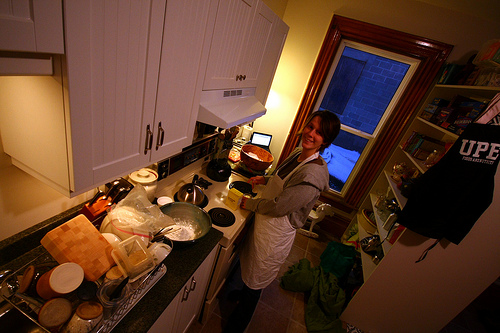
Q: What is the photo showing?
A: It is showing a kitchen.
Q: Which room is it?
A: It is a kitchen.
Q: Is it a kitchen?
A: Yes, it is a kitchen.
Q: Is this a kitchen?
A: Yes, it is a kitchen.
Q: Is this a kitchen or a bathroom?
A: It is a kitchen.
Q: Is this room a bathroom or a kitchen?
A: It is a kitchen.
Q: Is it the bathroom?
A: No, it is the kitchen.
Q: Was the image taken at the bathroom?
A: No, the picture was taken in the kitchen.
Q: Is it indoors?
A: Yes, it is indoors.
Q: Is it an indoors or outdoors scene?
A: It is indoors.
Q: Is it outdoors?
A: No, it is indoors.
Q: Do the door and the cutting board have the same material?
A: No, the door is made of glass and the cutting board is made of wood.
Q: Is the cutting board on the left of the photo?
A: Yes, the cutting board is on the left of the image.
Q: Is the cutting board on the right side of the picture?
A: No, the cutting board is on the left of the image.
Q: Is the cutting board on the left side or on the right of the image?
A: The cutting board is on the left of the image.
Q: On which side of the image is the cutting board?
A: The cutting board is on the left of the image.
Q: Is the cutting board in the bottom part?
A: Yes, the cutting board is in the bottom of the image.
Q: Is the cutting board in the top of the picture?
A: No, the cutting board is in the bottom of the image.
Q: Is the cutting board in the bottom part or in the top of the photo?
A: The cutting board is in the bottom of the image.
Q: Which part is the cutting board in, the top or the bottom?
A: The cutting board is in the bottom of the image.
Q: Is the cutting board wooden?
A: Yes, the cutting board is wooden.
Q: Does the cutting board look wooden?
A: Yes, the cutting board is wooden.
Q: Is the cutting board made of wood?
A: Yes, the cutting board is made of wood.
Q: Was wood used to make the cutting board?
A: Yes, the cutting board is made of wood.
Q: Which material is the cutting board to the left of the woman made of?
A: The cutting board is made of wood.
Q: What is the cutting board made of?
A: The cutting board is made of wood.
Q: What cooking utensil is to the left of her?
A: The cooking utensil is a cutting board.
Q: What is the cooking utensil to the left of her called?
A: The cooking utensil is a cutting board.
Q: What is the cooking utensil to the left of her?
A: The cooking utensil is a cutting board.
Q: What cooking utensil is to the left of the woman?
A: The cooking utensil is a cutting board.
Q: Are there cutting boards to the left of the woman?
A: Yes, there is a cutting board to the left of the woman.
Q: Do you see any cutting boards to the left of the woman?
A: Yes, there is a cutting board to the left of the woman.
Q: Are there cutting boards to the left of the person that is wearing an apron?
A: Yes, there is a cutting board to the left of the woman.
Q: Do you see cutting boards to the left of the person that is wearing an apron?
A: Yes, there is a cutting board to the left of the woman.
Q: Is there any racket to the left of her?
A: No, there is a cutting board to the left of the woman.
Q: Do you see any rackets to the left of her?
A: No, there is a cutting board to the left of the woman.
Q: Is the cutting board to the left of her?
A: Yes, the cutting board is to the left of the woman.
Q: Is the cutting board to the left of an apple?
A: No, the cutting board is to the left of the woman.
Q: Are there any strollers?
A: No, there are no strollers.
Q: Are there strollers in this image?
A: No, there are no strollers.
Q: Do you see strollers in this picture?
A: No, there are no strollers.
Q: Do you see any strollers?
A: No, there are no strollers.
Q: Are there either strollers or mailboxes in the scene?
A: No, there are no strollers or mailboxes.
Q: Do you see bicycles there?
A: No, there are no bicycles.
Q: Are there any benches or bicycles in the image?
A: No, there are no bicycles or benches.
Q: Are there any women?
A: Yes, there is a woman.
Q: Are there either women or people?
A: Yes, there is a woman.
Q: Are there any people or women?
A: Yes, there is a woman.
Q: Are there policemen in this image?
A: No, there are no policemen.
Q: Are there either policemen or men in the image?
A: No, there are no policemen or men.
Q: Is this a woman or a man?
A: This is a woman.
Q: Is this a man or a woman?
A: This is a woman.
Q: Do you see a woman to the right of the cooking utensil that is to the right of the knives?
A: Yes, there is a woman to the right of the kettle.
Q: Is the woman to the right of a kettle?
A: Yes, the woman is to the right of a kettle.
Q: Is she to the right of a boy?
A: No, the woman is to the right of a kettle.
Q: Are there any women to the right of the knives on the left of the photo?
A: Yes, there is a woman to the right of the knives.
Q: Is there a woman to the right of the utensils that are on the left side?
A: Yes, there is a woman to the right of the knives.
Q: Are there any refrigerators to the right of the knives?
A: No, there is a woman to the right of the knives.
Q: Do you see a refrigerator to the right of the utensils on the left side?
A: No, there is a woman to the right of the knives.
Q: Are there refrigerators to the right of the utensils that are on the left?
A: No, there is a woman to the right of the knives.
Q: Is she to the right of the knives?
A: Yes, the woman is to the right of the knives.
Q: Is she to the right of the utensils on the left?
A: Yes, the woman is to the right of the knives.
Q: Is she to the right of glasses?
A: No, the woman is to the right of the knives.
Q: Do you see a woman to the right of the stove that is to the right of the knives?
A: Yes, there is a woman to the right of the stove.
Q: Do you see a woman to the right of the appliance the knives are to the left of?
A: Yes, there is a woman to the right of the stove.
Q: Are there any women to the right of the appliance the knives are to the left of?
A: Yes, there is a woman to the right of the stove.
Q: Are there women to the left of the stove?
A: No, the woman is to the right of the stove.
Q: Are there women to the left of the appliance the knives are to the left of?
A: No, the woman is to the right of the stove.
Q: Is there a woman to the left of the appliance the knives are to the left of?
A: No, the woman is to the right of the stove.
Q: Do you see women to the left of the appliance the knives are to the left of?
A: No, the woman is to the right of the stove.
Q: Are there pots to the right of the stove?
A: No, there is a woman to the right of the stove.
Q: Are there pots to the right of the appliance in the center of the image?
A: No, there is a woman to the right of the stove.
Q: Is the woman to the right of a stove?
A: Yes, the woman is to the right of a stove.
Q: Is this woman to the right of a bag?
A: No, the woman is to the right of a stove.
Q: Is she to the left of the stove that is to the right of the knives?
A: No, the woman is to the right of the stove.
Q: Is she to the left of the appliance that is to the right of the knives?
A: No, the woman is to the right of the stove.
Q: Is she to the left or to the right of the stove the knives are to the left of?
A: The woman is to the right of the stove.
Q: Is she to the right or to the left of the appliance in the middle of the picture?
A: The woman is to the right of the stove.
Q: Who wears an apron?
A: The woman wears an apron.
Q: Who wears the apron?
A: The woman wears an apron.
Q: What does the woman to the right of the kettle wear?
A: The woman wears an apron.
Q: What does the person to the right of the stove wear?
A: The woman wears an apron.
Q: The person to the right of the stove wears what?
A: The woman wears an apron.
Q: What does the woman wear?
A: The woman wears an apron.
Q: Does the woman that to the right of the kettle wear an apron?
A: Yes, the woman wears an apron.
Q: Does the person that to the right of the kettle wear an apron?
A: Yes, the woman wears an apron.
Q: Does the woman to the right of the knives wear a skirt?
A: No, the woman wears an apron.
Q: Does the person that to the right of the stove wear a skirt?
A: No, the woman wears an apron.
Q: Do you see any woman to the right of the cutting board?
A: Yes, there is a woman to the right of the cutting board.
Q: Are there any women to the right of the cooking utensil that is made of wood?
A: Yes, there is a woman to the right of the cutting board.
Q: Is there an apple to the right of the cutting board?
A: No, there is a woman to the right of the cutting board.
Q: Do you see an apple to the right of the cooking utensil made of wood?
A: No, there is a woman to the right of the cutting board.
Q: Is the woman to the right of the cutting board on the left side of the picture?
A: Yes, the woman is to the right of the cutting board.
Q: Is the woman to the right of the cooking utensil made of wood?
A: Yes, the woman is to the right of the cutting board.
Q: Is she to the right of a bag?
A: No, the woman is to the right of the cutting board.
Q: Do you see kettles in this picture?
A: Yes, there is a kettle.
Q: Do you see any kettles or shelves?
A: Yes, there is a kettle.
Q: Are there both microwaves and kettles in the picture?
A: No, there is a kettle but no microwaves.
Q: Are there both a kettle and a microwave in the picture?
A: No, there is a kettle but no microwaves.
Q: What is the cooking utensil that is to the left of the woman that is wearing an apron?
A: The cooking utensil is a kettle.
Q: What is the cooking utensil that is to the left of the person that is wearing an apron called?
A: The cooking utensil is a kettle.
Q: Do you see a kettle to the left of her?
A: Yes, there is a kettle to the left of the woman.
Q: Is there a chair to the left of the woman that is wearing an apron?
A: No, there is a kettle to the left of the woman.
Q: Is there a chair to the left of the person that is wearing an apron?
A: No, there is a kettle to the left of the woman.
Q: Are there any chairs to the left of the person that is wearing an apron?
A: No, there is a kettle to the left of the woman.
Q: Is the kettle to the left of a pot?
A: No, the kettle is to the left of the woman.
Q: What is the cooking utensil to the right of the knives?
A: The cooking utensil is a kettle.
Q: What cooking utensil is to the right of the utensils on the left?
A: The cooking utensil is a kettle.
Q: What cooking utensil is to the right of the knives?
A: The cooking utensil is a kettle.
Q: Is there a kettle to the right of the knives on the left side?
A: Yes, there is a kettle to the right of the knives.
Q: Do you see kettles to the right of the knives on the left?
A: Yes, there is a kettle to the right of the knives.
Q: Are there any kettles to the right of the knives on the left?
A: Yes, there is a kettle to the right of the knives.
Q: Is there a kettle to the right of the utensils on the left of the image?
A: Yes, there is a kettle to the right of the knives.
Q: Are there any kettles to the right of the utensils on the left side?
A: Yes, there is a kettle to the right of the knives.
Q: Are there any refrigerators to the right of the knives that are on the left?
A: No, there is a kettle to the right of the knives.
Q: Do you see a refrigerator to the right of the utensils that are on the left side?
A: No, there is a kettle to the right of the knives.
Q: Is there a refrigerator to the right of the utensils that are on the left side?
A: No, there is a kettle to the right of the knives.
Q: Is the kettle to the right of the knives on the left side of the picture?
A: Yes, the kettle is to the right of the knives.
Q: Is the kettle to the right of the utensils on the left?
A: Yes, the kettle is to the right of the knives.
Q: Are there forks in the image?
A: No, there are no forks.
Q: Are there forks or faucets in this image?
A: No, there are no forks or faucets.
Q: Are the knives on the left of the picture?
A: Yes, the knives are on the left of the image.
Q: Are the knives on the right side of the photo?
A: No, the knives are on the left of the image.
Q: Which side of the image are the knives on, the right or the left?
A: The knives are on the left of the image.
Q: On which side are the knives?
A: The knives are on the left of the image.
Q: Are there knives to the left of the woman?
A: Yes, there are knives to the left of the woman.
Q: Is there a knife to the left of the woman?
A: Yes, there are knives to the left of the woman.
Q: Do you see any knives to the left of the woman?
A: Yes, there are knives to the left of the woman.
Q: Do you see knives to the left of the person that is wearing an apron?
A: Yes, there are knives to the left of the woman.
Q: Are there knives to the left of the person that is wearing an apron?
A: Yes, there are knives to the left of the woman.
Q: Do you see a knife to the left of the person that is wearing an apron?
A: Yes, there are knives to the left of the woman.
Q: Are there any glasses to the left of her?
A: No, there are knives to the left of the woman.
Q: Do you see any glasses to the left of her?
A: No, there are knives to the left of the woman.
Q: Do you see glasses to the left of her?
A: No, there are knives to the left of the woman.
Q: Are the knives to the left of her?
A: Yes, the knives are to the left of a woman.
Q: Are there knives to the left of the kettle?
A: Yes, there are knives to the left of the kettle.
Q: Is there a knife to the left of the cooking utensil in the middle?
A: Yes, there are knives to the left of the kettle.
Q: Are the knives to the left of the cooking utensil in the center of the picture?
A: Yes, the knives are to the left of the kettle.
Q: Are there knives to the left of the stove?
A: Yes, there are knives to the left of the stove.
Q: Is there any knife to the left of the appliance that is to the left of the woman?
A: Yes, there are knives to the left of the stove.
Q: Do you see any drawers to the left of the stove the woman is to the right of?
A: No, there are knives to the left of the stove.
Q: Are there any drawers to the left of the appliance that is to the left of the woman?
A: No, there are knives to the left of the stove.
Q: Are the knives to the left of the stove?
A: Yes, the knives are to the left of the stove.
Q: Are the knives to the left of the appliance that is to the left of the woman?
A: Yes, the knives are to the left of the stove.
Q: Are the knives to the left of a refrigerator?
A: No, the knives are to the left of the stove.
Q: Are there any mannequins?
A: No, there are no mannequins.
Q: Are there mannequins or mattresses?
A: No, there are no mannequins or mattresses.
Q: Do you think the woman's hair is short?
A: Yes, the hair is short.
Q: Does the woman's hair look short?
A: Yes, the hair is short.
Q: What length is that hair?
A: The hair is short.